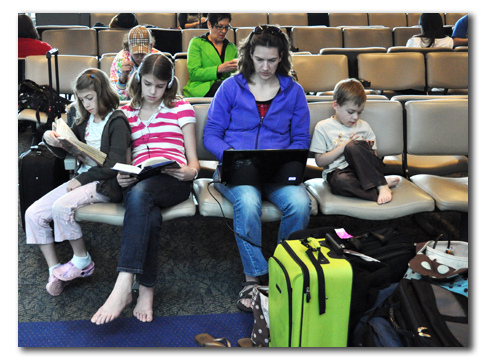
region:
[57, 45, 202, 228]
the girls are reading books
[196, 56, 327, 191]
the jacket is purple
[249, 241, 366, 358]
the suitcase is yellow green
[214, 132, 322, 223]
the laptop is black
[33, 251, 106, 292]
the sandals are pink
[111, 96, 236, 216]
the shirt is stripes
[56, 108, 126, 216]
the jacket is gray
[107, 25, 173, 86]
the woman is wearing a cap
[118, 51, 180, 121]
the girl is wearing a headphones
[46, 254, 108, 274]
the socks are white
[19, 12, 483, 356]
Interior scene, light source uncertain.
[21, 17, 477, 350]
Picture taken inside man-made public area, featuring people.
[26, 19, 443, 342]
Area with brown, metal and plastic connected chairs.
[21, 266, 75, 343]
Grey and blue carpet on floor.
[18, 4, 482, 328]
People, scattered throughout chairs.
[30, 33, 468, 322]
Grouping of probably related people on front row of chairs.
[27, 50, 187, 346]
Young girls, reading and sharing chair.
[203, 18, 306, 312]
Woman in jeans and jacket, supporting laptop she is working on.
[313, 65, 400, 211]
Small boy, curled on chair and drawing.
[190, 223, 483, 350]
Luggage and personal items, piled in front of family grouping.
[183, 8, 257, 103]
woman in green jacket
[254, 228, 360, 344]
green suitcase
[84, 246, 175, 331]
girl with bare feet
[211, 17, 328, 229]
woman on a laptop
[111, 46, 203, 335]
girl in a stripped shirt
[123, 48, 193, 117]
girl in pig tails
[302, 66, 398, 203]
boy playing on a device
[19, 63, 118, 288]
girl reading a book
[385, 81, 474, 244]
chair at an airport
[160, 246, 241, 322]
patterned carpet at airport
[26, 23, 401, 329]
a woman and 3 children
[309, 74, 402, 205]
a boy wearing a tan shirt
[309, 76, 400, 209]
a boy wearing brown pants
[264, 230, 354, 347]
a lime green suitcase can be seen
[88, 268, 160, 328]
bare feet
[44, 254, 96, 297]
pink shoes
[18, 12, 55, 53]
a woman wearing red can be seen in the background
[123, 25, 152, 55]
a baseball cap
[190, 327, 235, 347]
a brown flip flop sandal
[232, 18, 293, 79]
a woman with brown hair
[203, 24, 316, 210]
Woman working on a laptop computer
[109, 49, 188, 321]
Young girl is reading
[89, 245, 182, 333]
A person is barefooted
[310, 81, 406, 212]
A young boy has his feet on his chair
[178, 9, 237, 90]
Lady is wearing a green blazer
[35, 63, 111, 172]
Girl is reading a book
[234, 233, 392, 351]
Green suitcase on the floor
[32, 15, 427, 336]
Everyone is waiting to travel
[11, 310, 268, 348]
Blue carpet on the floor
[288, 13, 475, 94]
Many brown chairs